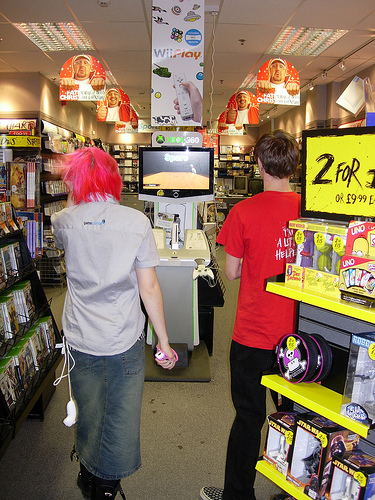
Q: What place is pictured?
A: It is a store.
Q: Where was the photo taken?
A: It was taken at the store.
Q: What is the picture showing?
A: It is showing a store.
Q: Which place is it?
A: It is a store.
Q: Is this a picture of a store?
A: Yes, it is showing a store.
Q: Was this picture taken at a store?
A: Yes, it was taken in a store.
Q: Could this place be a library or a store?
A: It is a store.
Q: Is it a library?
A: No, it is a store.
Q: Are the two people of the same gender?
A: No, they are both male and female.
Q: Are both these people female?
A: No, they are both male and female.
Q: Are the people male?
A: No, they are both male and female.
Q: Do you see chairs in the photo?
A: No, there are no chairs.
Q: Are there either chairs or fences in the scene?
A: No, there are no chairs or fences.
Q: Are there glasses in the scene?
A: No, there are no glasses.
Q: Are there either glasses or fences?
A: No, there are no glasses or fences.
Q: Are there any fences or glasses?
A: No, there are no glasses or fences.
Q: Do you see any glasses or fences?
A: No, there are no glasses or fences.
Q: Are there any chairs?
A: No, there are no chairs.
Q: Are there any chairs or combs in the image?
A: No, there are no chairs or combs.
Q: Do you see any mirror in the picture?
A: No, there are no mirrors.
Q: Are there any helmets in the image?
A: No, there are no helmets.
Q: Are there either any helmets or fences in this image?
A: No, there are no helmets or fences.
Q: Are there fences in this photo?
A: No, there are no fences.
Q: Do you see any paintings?
A: No, there are no paintings.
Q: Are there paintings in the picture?
A: No, there are no paintings.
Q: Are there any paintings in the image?
A: No, there are no paintings.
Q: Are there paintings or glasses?
A: No, there are no paintings or glasses.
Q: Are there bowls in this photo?
A: No, there are no bowls.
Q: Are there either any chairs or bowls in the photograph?
A: No, there are no bowls or chairs.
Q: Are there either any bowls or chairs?
A: No, there are no bowls or chairs.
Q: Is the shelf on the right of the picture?
A: Yes, the shelf is on the right of the image.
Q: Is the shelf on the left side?
A: No, the shelf is on the right of the image.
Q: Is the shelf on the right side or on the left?
A: The shelf is on the right of the image.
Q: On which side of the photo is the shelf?
A: The shelf is on the right of the image.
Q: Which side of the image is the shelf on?
A: The shelf is on the right of the image.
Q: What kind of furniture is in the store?
A: The piece of furniture is a shelf.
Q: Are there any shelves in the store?
A: Yes, there is a shelf in the store.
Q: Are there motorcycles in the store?
A: No, there is a shelf in the store.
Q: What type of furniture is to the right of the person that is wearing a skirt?
A: The piece of furniture is a shelf.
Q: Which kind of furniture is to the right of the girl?
A: The piece of furniture is a shelf.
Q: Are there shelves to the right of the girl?
A: Yes, there is a shelf to the right of the girl.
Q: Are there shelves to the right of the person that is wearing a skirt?
A: Yes, there is a shelf to the right of the girl.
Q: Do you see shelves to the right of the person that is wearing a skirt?
A: Yes, there is a shelf to the right of the girl.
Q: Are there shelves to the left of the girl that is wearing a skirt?
A: No, the shelf is to the right of the girl.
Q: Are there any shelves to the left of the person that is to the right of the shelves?
A: No, the shelf is to the right of the girl.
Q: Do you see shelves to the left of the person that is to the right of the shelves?
A: No, the shelf is to the right of the girl.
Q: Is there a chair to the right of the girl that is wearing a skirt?
A: No, there is a shelf to the right of the girl.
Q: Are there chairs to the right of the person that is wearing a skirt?
A: No, there is a shelf to the right of the girl.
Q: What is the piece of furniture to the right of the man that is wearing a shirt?
A: The piece of furniture is a shelf.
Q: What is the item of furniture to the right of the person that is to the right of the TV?
A: The piece of furniture is a shelf.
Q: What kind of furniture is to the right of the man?
A: The piece of furniture is a shelf.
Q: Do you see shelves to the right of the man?
A: Yes, there is a shelf to the right of the man.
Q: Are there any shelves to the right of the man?
A: Yes, there is a shelf to the right of the man.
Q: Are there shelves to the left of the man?
A: No, the shelf is to the right of the man.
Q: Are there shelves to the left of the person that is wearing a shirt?
A: No, the shelf is to the right of the man.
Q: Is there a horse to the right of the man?
A: No, there is a shelf to the right of the man.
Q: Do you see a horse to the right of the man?
A: No, there is a shelf to the right of the man.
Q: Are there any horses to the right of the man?
A: No, there is a shelf to the right of the man.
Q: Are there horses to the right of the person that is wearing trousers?
A: No, there is a shelf to the right of the man.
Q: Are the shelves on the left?
A: Yes, the shelves are on the left of the image.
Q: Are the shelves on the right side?
A: No, the shelves are on the left of the image.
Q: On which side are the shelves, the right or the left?
A: The shelves are on the left of the image.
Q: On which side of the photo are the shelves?
A: The shelves are on the left of the image.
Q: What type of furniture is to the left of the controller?
A: The pieces of furniture are shelves.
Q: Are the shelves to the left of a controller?
A: Yes, the shelves are to the left of a controller.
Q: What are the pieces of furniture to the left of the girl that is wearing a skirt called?
A: The pieces of furniture are shelves.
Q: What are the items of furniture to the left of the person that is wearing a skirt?
A: The pieces of furniture are shelves.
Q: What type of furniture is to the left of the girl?
A: The pieces of furniture are shelves.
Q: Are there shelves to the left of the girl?
A: Yes, there are shelves to the left of the girl.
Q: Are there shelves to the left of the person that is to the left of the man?
A: Yes, there are shelves to the left of the girl.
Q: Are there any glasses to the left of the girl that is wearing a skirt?
A: No, there are shelves to the left of the girl.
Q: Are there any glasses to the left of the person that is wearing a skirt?
A: No, there are shelves to the left of the girl.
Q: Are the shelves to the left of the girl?
A: Yes, the shelves are to the left of the girl.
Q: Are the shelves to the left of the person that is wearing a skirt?
A: Yes, the shelves are to the left of the girl.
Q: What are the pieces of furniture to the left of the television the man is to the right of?
A: The pieces of furniture are shelves.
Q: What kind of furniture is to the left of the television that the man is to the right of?
A: The pieces of furniture are shelves.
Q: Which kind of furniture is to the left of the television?
A: The pieces of furniture are shelves.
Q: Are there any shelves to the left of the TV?
A: Yes, there are shelves to the left of the TV.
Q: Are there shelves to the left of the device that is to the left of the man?
A: Yes, there are shelves to the left of the TV.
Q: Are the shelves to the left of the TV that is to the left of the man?
A: Yes, the shelves are to the left of the television.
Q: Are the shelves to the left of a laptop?
A: No, the shelves are to the left of the television.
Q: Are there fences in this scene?
A: No, there are no fences.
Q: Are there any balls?
A: No, there are no balls.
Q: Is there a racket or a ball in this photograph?
A: No, there are no balls or rackets.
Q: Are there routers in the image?
A: No, there are no routers.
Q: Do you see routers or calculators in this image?
A: No, there are no routers or calculators.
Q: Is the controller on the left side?
A: Yes, the controller is on the left of the image.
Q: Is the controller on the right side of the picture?
A: No, the controller is on the left of the image.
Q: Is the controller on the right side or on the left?
A: The controller is on the left of the image.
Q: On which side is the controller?
A: The controller is on the left of the image.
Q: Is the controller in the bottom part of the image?
A: Yes, the controller is in the bottom of the image.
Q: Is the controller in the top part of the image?
A: No, the controller is in the bottom of the image.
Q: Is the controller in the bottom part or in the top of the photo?
A: The controller is in the bottom of the image.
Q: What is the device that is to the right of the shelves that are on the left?
A: The device is a controller.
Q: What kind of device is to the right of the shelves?
A: The device is a controller.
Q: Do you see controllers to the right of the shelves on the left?
A: Yes, there is a controller to the right of the shelves.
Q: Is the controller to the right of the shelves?
A: Yes, the controller is to the right of the shelves.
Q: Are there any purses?
A: Yes, there is a purse.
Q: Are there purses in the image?
A: Yes, there is a purse.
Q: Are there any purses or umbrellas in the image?
A: Yes, there is a purse.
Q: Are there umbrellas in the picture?
A: No, there are no umbrellas.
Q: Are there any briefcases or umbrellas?
A: No, there are no umbrellas or briefcases.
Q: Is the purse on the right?
A: Yes, the purse is on the right of the image.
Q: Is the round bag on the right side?
A: Yes, the purse is on the right of the image.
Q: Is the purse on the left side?
A: No, the purse is on the right of the image.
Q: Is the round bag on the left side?
A: No, the purse is on the right of the image.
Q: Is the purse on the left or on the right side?
A: The purse is on the right of the image.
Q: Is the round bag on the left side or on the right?
A: The purse is on the right of the image.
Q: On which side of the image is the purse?
A: The purse is on the right of the image.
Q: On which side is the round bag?
A: The purse is on the right of the image.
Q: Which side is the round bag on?
A: The purse is on the right of the image.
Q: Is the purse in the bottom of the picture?
A: Yes, the purse is in the bottom of the image.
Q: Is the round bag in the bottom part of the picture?
A: Yes, the purse is in the bottom of the image.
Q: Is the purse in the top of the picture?
A: No, the purse is in the bottom of the image.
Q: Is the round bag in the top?
A: No, the purse is in the bottom of the image.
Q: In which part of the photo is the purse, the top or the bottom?
A: The purse is in the bottom of the image.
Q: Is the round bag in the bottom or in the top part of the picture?
A: The purse is in the bottom of the image.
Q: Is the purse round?
A: Yes, the purse is round.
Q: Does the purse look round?
A: Yes, the purse is round.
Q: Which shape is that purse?
A: The purse is round.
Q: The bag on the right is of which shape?
A: The purse is round.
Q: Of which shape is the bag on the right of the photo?
A: The purse is round.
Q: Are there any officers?
A: No, there are no officers.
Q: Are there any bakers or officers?
A: No, there are no officers or bakers.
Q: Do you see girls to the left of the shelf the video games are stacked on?
A: Yes, there is a girl to the left of the shelf.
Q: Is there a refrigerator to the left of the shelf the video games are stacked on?
A: No, there is a girl to the left of the shelf.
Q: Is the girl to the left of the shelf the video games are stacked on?
A: Yes, the girl is to the left of the shelf.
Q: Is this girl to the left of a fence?
A: No, the girl is to the left of the shelf.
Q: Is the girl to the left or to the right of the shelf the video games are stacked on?
A: The girl is to the left of the shelf.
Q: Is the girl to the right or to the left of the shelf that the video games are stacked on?
A: The girl is to the left of the shelf.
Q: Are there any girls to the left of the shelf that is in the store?
A: Yes, there is a girl to the left of the shelf.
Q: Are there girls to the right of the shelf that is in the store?
A: No, the girl is to the left of the shelf.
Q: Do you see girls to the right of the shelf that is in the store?
A: No, the girl is to the left of the shelf.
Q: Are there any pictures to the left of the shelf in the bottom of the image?
A: No, there is a girl to the left of the shelf.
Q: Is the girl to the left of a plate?
A: No, the girl is to the left of the shelf.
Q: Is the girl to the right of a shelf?
A: No, the girl is to the left of a shelf.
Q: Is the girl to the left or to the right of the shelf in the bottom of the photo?
A: The girl is to the left of the shelf.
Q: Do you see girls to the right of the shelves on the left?
A: Yes, there is a girl to the right of the shelves.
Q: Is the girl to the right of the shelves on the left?
A: Yes, the girl is to the right of the shelves.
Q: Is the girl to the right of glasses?
A: No, the girl is to the right of the shelves.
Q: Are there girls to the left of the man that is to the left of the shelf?
A: Yes, there is a girl to the left of the man.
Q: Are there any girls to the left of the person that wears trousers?
A: Yes, there is a girl to the left of the man.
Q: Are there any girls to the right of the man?
A: No, the girl is to the left of the man.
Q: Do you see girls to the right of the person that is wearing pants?
A: No, the girl is to the left of the man.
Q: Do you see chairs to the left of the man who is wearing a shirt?
A: No, there is a girl to the left of the man.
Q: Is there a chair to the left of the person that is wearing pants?
A: No, there is a girl to the left of the man.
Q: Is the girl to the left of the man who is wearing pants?
A: Yes, the girl is to the left of the man.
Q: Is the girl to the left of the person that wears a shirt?
A: Yes, the girl is to the left of the man.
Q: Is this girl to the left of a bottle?
A: No, the girl is to the left of the man.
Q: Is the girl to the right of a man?
A: No, the girl is to the left of a man.